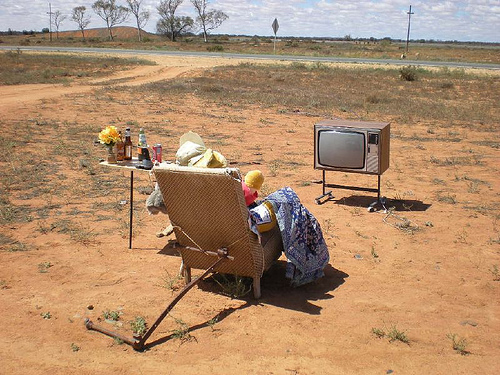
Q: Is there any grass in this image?
A: Yes, there is grass.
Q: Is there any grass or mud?
A: Yes, there is grass.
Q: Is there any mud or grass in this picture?
A: Yes, there is grass.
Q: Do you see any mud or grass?
A: Yes, there is grass.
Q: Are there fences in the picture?
A: No, there are no fences.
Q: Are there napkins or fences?
A: No, there are no fences or napkins.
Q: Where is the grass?
A: The grass is on the ground.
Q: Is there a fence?
A: No, there are no fences.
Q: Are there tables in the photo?
A: Yes, there is a table.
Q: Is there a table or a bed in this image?
A: Yes, there is a table.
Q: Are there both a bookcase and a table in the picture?
A: No, there is a table but no bookcases.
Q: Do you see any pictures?
A: No, there are no pictures.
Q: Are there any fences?
A: No, there are no fences.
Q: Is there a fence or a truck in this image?
A: No, there are no fences or trucks.